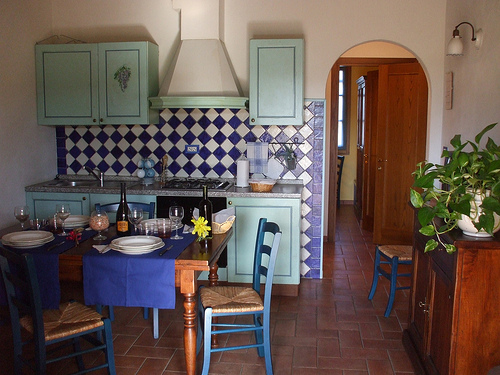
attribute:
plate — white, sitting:
[112, 237, 161, 247]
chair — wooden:
[193, 267, 268, 335]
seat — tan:
[196, 284, 265, 314]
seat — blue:
[186, 281, 262, 328]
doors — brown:
[364, 53, 427, 248]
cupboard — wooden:
[398, 198, 495, 370]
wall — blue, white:
[299, 22, 351, 49]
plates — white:
[105, 229, 168, 258]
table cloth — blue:
[78, 257, 186, 312]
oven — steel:
[155, 194, 230, 271]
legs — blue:
[368, 246, 413, 318]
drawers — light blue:
[26, 35, 153, 139]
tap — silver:
[80, 163, 105, 189]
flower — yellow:
[187, 210, 214, 241]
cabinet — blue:
[37, 48, 102, 125]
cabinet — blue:
[98, 40, 142, 120]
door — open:
[368, 61, 428, 250]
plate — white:
[112, 240, 164, 254]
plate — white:
[4, 229, 56, 241]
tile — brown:
[336, 303, 354, 315]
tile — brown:
[339, 330, 364, 348]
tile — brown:
[294, 344, 317, 366]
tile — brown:
[295, 325, 337, 339]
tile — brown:
[358, 320, 383, 340]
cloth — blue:
[84, 226, 196, 307]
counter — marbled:
[270, 176, 301, 198]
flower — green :
[405, 121, 497, 258]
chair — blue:
[193, 214, 288, 374]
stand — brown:
[400, 208, 499, 373]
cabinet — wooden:
[399, 198, 499, 373]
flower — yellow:
[189, 215, 212, 240]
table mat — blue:
[83, 223, 196, 310]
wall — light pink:
[471, 77, 487, 89]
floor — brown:
[299, 267, 344, 373]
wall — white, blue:
[166, 120, 231, 137]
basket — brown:
[246, 174, 283, 195]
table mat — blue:
[81, 249, 182, 313]